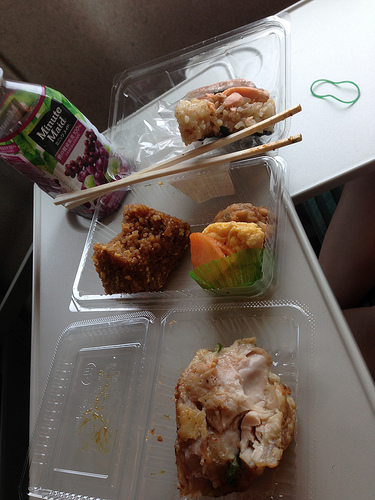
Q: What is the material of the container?
A: Plastic.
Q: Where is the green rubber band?
A: Upper right corner.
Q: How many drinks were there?
A: One.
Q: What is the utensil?
A: Chopsticks.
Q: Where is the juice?
A: Upper left corner.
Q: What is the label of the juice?
A: Minute Maid.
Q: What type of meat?
A: Chicken.